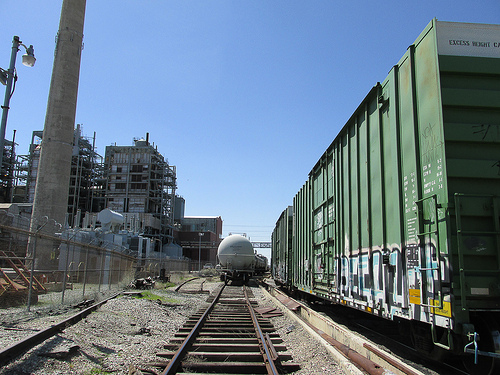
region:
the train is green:
[265, 114, 440, 249]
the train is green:
[257, 216, 381, 369]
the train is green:
[205, 150, 492, 347]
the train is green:
[321, 199, 452, 372]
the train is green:
[316, 239, 358, 321]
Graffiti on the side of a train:
[261, 211, 446, 301]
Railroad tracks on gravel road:
[135, 276, 299, 373]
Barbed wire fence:
[1, 194, 148, 284]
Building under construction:
[46, 133, 194, 240]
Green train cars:
[255, 139, 488, 367]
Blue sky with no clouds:
[133, 7, 359, 124]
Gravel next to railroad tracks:
[101, 247, 191, 361]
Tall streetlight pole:
[0, 16, 37, 164]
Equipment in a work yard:
[3, 233, 83, 305]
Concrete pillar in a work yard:
[33, 0, 85, 264]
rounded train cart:
[209, 222, 264, 276]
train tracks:
[168, 281, 284, 361]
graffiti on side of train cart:
[305, 221, 457, 339]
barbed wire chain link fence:
[23, 205, 150, 333]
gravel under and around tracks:
[107, 305, 172, 368]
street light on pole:
[11, 23, 54, 85]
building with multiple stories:
[107, 140, 179, 207]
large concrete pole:
[31, 5, 97, 220]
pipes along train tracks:
[20, 296, 90, 347]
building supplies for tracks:
[261, 291, 304, 319]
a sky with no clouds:
[4, 1, 499, 255]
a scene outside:
[7, 5, 489, 368]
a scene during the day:
[9, 10, 496, 369]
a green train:
[270, 12, 499, 367]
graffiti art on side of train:
[323, 226, 475, 331]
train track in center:
[143, 260, 309, 373]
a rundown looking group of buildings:
[0, 94, 225, 284]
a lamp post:
[0, 27, 42, 186]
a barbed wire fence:
[0, 210, 212, 326]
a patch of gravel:
[5, 282, 205, 372]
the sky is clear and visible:
[170, 104, 297, 259]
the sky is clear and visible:
[216, 140, 321, 367]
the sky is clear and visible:
[210, 108, 280, 238]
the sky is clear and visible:
[180, 155, 290, 351]